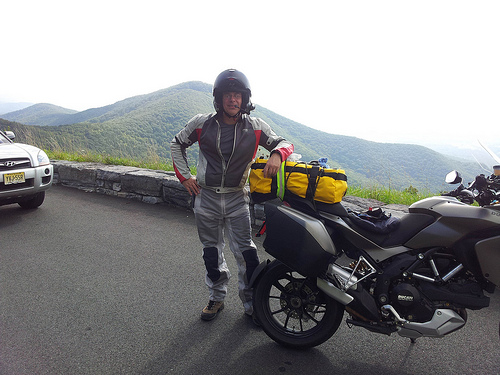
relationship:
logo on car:
[0, 156, 17, 170] [0, 122, 56, 222]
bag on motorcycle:
[242, 138, 374, 209] [245, 149, 498, 353]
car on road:
[1, 128, 59, 216] [38, 200, 193, 324]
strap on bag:
[251, 161, 350, 176] [249, 151, 354, 206]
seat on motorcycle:
[337, 196, 444, 251] [245, 149, 498, 353]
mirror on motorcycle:
[444, 167, 459, 185] [248, 168, 498, 346]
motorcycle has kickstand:
[245, 149, 498, 353] [396, 336, 414, 371]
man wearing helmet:
[168, 65, 294, 325] [213, 68, 255, 117]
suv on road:
[1, 123, 53, 213] [0, 172, 500, 373]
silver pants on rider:
[189, 192, 264, 303] [158, 55, 288, 327]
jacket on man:
[169, 107, 283, 179] [176, 73, 298, 278]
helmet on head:
[211, 68, 252, 103] [212, 67, 252, 121]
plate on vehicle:
[224, 179, 305, 246] [278, 173, 498, 313]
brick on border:
[97, 163, 169, 217] [54, 148, 194, 228]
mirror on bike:
[445, 170, 463, 184] [245, 150, 498, 362]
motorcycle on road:
[245, 149, 498, 353] [45, 228, 167, 338]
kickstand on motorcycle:
[397, 333, 426, 369] [245, 149, 498, 353]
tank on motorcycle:
[267, 222, 322, 281] [254, 154, 498, 365]